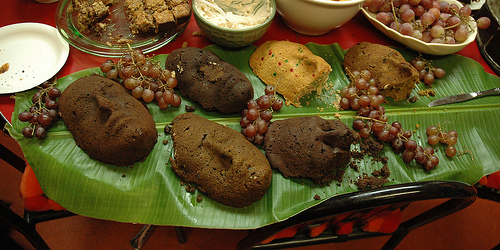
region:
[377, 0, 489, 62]
Red grapes in a bowl.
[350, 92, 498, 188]
Red grapes on a leaf.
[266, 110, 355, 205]
Chocolate cookies on a leaf.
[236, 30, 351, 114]
Sprinkled cookie on a leaf.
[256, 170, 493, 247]
Black metal back of a chair.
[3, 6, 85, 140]
Empty white paper plate.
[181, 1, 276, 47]
A bowlof white frosting.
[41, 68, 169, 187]
Cookie shaped like a face.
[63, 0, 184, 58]
Glass dish with a desert in it.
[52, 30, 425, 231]
Six cookies looking like faces.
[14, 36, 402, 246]
Food in the shape of faces.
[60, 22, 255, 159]
Grapes on the table.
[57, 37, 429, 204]
Faces on the table.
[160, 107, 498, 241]
Chair at the table.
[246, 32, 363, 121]
Half eaten food face.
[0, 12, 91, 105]
White plate on the table.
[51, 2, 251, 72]
Brownies on a plate.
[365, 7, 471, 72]
Grapes in a bowl.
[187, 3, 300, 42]
Dip in a bowl.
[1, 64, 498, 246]
Green cloth on the table.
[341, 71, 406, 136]
a bunch of red grapes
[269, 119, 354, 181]
a bread in the shape of a face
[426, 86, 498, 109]
a butter knife on the table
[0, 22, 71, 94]
a nearly empty plate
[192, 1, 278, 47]
a green bowl sitting on the table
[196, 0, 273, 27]
a white, creamy dip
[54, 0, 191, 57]
a glass plate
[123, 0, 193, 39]
a cluster of desserts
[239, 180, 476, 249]
a black, metal chair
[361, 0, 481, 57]
a white dish holding grapes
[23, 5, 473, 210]
foods on top of a table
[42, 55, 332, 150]
clusters of grapes next to cakes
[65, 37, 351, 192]
cakes in the shape of human faces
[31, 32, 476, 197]
food displayed on one large leaf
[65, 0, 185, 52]
squares of dark cake on a glass plate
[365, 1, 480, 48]
grapes inside an oval bowl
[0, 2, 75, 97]
white plate with a few crumbs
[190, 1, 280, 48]
creamy filling in a bowl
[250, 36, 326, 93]
cake with red and green dots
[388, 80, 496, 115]
knife on top of leaf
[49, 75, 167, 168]
Complete face brown cake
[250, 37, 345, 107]
Face no chin yellow cake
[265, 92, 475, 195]
Half face could eat grapes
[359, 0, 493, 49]
Red grapes white bowl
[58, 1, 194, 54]
Clear plate chocolate brownies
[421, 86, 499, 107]
Flatware knife available cut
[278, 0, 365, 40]
Deep tan bowl unknown contents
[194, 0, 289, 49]
Either frosting or cream cheese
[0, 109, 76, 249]
Wood chair red cushion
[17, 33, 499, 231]
Represents tropical green leaf